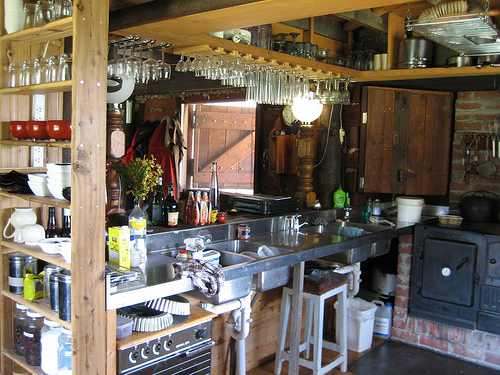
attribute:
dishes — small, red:
[7, 119, 74, 139]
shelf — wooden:
[1, 138, 74, 148]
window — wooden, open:
[184, 103, 255, 190]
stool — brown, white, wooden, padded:
[273, 275, 353, 373]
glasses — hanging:
[107, 33, 175, 86]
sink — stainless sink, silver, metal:
[298, 221, 400, 262]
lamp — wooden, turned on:
[290, 95, 321, 204]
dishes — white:
[25, 162, 73, 200]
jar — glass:
[20, 311, 41, 365]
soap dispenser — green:
[363, 196, 372, 217]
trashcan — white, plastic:
[333, 293, 378, 353]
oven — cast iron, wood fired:
[409, 219, 499, 334]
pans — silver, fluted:
[118, 293, 192, 331]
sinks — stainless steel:
[161, 237, 294, 308]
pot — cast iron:
[458, 186, 499, 222]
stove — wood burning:
[416, 211, 499, 234]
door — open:
[192, 105, 250, 191]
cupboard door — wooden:
[361, 85, 454, 199]